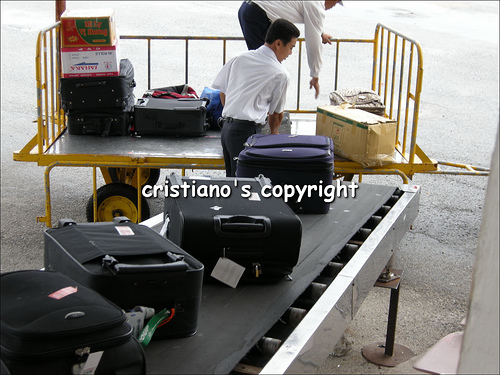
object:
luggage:
[167, 170, 305, 284]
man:
[210, 17, 304, 177]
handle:
[222, 220, 266, 235]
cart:
[10, 16, 496, 231]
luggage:
[133, 95, 205, 139]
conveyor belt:
[131, 178, 401, 375]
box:
[315, 100, 396, 167]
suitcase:
[234, 132, 338, 216]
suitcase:
[159, 170, 302, 286]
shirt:
[211, 45, 293, 127]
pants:
[221, 121, 262, 178]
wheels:
[84, 181, 151, 224]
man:
[235, 0, 335, 99]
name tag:
[211, 256, 248, 289]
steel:
[360, 269, 416, 368]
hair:
[266, 17, 302, 46]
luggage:
[1, 270, 148, 375]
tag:
[48, 285, 79, 303]